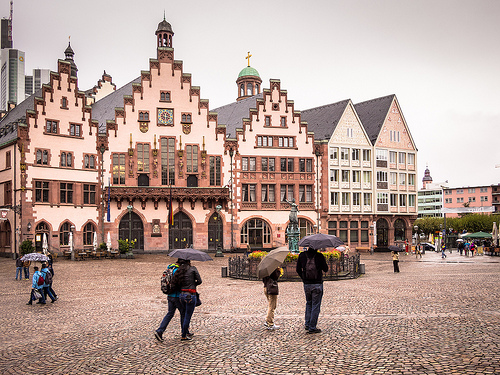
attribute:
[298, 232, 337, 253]
umbrella — black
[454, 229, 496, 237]
tent — green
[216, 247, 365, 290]
fence — circular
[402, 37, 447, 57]
sky — overcast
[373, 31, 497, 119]
sky — cloudy